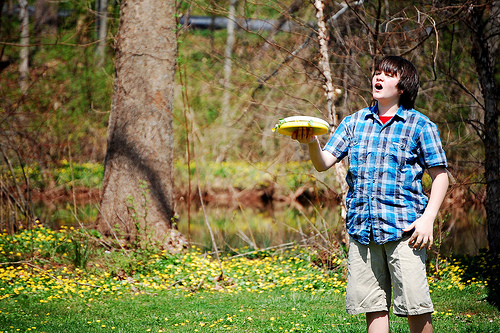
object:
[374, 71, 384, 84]
nose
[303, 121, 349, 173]
arm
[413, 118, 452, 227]
arm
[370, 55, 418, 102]
head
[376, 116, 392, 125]
t-shirt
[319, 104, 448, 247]
blue shirt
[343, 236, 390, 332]
leg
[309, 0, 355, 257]
tree trunk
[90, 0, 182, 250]
tree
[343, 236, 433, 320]
shorts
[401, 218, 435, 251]
hand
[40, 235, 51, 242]
yellow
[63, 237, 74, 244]
flowers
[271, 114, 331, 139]
frisbees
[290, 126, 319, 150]
hand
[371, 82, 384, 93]
mouth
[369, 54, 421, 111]
black hair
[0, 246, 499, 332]
grass/flowers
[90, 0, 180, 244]
tree trunk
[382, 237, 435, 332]
leg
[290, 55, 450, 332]
boy